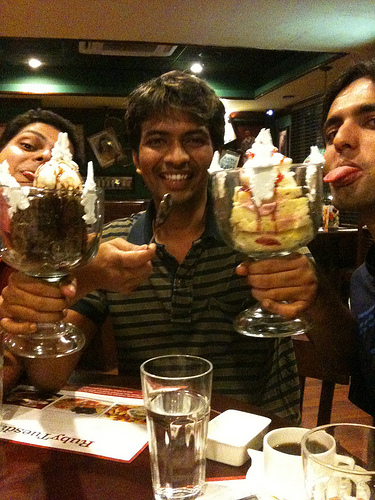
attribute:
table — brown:
[5, 371, 358, 499]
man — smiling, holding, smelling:
[78, 72, 331, 405]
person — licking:
[293, 53, 375, 234]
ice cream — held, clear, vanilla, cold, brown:
[9, 124, 335, 360]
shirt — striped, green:
[70, 206, 319, 418]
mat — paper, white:
[2, 362, 174, 468]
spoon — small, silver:
[126, 179, 178, 243]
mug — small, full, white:
[244, 419, 357, 492]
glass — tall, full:
[140, 354, 215, 498]